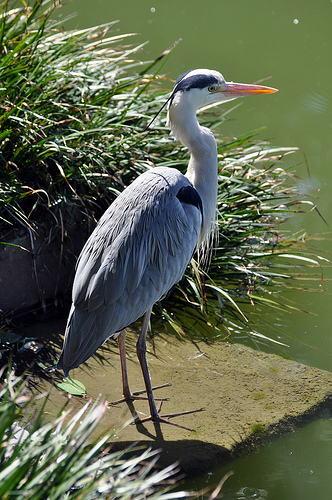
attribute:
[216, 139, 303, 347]
grass — green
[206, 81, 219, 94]
eye — yellow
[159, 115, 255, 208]
neck — white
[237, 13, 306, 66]
water — reflection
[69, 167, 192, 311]
feathers — white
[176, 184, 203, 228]
streak — black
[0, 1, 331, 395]
grass — green, spiky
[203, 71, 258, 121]
beek — orange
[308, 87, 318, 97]
ground — white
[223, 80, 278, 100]
beak — orange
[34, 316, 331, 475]
cement — brown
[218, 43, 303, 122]
beak — long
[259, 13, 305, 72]
water — green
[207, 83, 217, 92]
eye — yellow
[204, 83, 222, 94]
eye — open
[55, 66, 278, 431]
bird — grey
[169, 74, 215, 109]
streak — black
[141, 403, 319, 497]
water — green, mucky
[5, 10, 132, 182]
bush — green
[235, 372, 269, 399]
ground — part of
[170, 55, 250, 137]
head — black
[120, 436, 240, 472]
shadow — part